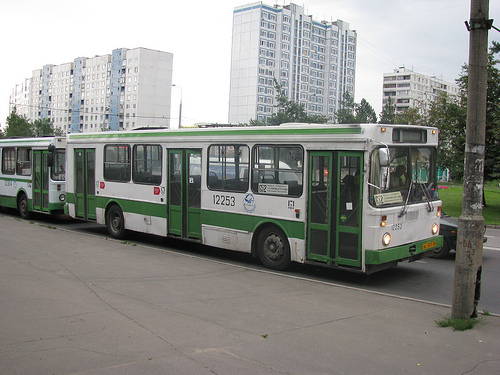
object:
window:
[251, 144, 304, 199]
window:
[206, 144, 249, 195]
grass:
[435, 314, 478, 330]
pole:
[449, 0, 492, 320]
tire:
[252, 223, 288, 271]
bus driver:
[389, 160, 411, 193]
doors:
[332, 148, 363, 270]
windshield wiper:
[399, 175, 419, 217]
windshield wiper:
[415, 178, 434, 213]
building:
[225, 0, 360, 125]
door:
[308, 151, 335, 264]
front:
[363, 126, 445, 263]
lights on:
[379, 218, 388, 229]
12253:
[213, 195, 239, 207]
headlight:
[381, 232, 394, 244]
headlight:
[430, 224, 442, 233]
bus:
[0, 133, 65, 220]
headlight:
[56, 193, 67, 202]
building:
[8, 45, 173, 137]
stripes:
[105, 45, 122, 132]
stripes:
[69, 58, 84, 130]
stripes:
[37, 63, 49, 129]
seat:
[386, 173, 406, 193]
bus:
[62, 111, 457, 283]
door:
[72, 147, 89, 219]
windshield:
[366, 142, 441, 210]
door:
[166, 146, 183, 240]